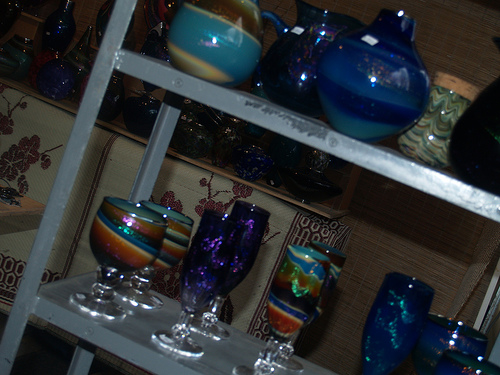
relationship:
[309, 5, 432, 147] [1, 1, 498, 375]
vase on top of unit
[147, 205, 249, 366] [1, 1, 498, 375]
glasses on unit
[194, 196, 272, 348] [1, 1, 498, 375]
glasses on unit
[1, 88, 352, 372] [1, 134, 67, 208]
tapestry with flowers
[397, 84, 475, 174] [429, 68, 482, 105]
glass with cork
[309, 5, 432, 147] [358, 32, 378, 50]
vase with sticker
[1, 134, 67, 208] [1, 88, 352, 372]
flowers in tapestry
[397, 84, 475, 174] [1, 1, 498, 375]
glass on top of unit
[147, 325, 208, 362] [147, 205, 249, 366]
bottom of glasses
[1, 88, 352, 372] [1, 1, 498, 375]
tapestry behind unit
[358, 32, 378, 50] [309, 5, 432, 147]
sticker on vase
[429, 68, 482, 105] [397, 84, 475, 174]
cork to glass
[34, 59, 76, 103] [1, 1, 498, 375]
glass behind unit